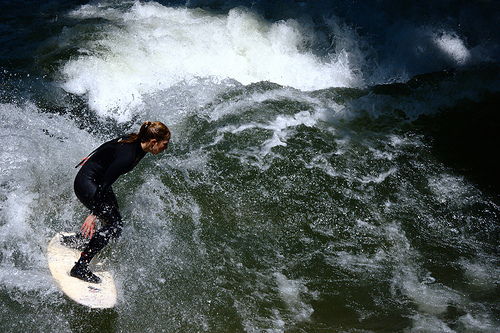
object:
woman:
[60, 120, 171, 284]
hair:
[120, 121, 171, 153]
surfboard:
[46, 232, 117, 308]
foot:
[69, 252, 102, 284]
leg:
[74, 180, 123, 262]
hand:
[80, 214, 97, 239]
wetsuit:
[74, 134, 149, 216]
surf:
[60, 0, 380, 122]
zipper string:
[74, 141, 109, 168]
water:
[319, 296, 405, 328]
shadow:
[0, 0, 500, 201]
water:
[0, 0, 499, 333]